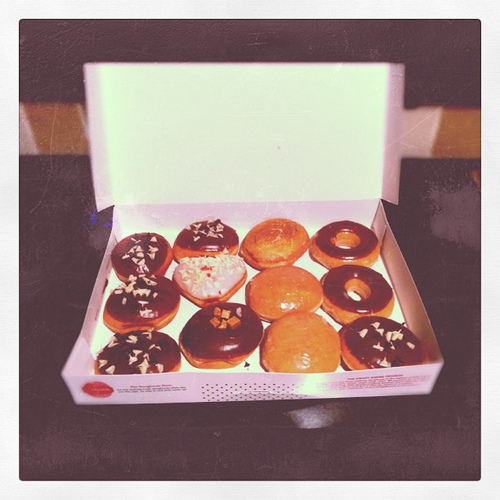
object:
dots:
[260, 379, 269, 387]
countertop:
[18, 19, 480, 480]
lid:
[80, 61, 405, 213]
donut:
[107, 229, 173, 281]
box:
[58, 58, 443, 410]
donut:
[171, 218, 237, 264]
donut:
[238, 216, 311, 269]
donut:
[311, 218, 381, 267]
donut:
[320, 262, 394, 326]